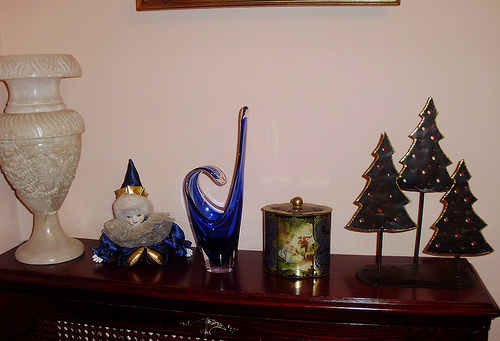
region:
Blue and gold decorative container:
[262, 196, 332, 278]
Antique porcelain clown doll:
[91, 156, 194, 271]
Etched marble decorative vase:
[0, 52, 85, 265]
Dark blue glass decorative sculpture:
[182, 105, 248, 276]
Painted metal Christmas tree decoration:
[345, 95, 494, 289]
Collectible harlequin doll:
[92, 155, 192, 264]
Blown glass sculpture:
[182, 106, 247, 273]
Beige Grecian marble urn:
[0, 54, 86, 264]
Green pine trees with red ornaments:
[348, 96, 494, 290]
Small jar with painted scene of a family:
[262, 197, 331, 278]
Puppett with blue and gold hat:
[92, 155, 174, 281]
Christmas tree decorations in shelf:
[337, 89, 497, 309]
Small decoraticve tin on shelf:
[255, 178, 332, 300]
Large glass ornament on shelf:
[161, 88, 249, 303]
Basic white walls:
[122, 50, 331, 94]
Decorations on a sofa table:
[7, 50, 498, 323]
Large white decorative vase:
[1, 29, 98, 296]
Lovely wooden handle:
[172, 312, 250, 339]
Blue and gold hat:
[105, 155, 155, 197]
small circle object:
[285, 188, 310, 211]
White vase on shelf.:
[16, 48, 81, 243]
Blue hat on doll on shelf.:
[114, 159, 164, 211]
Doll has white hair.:
[116, 190, 167, 228]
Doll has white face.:
[119, 210, 164, 239]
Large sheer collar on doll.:
[107, 204, 185, 245]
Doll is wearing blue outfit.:
[101, 224, 196, 270]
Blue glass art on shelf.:
[186, 102, 251, 275]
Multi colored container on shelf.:
[262, 187, 328, 287]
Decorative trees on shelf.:
[338, 124, 485, 331]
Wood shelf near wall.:
[34, 244, 478, 333]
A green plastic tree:
[356, 128, 408, 236]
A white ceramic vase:
[4, 46, 84, 261]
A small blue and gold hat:
[118, 159, 145, 194]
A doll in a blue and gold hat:
[93, 151, 174, 275]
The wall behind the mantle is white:
[293, 70, 357, 180]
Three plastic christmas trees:
[362, 98, 482, 288]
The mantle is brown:
[353, 275, 467, 300]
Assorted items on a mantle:
[3, 81, 486, 261]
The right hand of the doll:
[88, 247, 105, 264]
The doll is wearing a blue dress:
[98, 221, 185, 252]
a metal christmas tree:
[398, 93, 451, 198]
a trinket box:
[253, 186, 336, 281]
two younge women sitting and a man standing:
[272, 216, 316, 275]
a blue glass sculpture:
[181, 104, 252, 274]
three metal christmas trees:
[342, 93, 496, 294]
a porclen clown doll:
[83, 158, 197, 273]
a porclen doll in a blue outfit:
[84, 161, 193, 272]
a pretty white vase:
[1, 51, 86, 266]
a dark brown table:
[1, 233, 499, 339]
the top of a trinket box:
[264, 195, 329, 217]